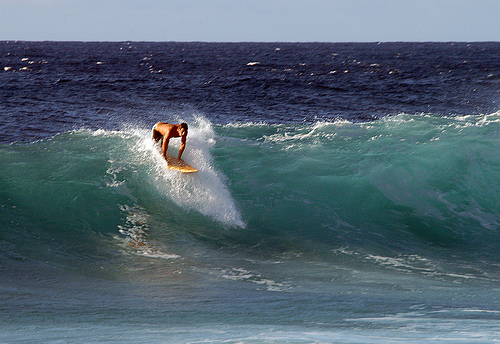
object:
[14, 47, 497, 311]
ocean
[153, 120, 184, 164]
man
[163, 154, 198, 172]
board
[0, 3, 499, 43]
sky